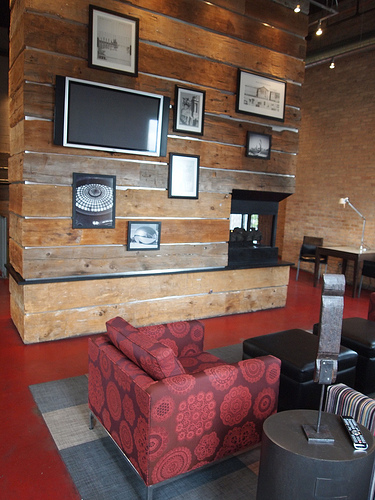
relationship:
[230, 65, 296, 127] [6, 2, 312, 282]
picture hanging from wall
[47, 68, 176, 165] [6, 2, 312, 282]
tv hanging on wall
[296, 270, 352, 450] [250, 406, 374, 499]
lamp on top of table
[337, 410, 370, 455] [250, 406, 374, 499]
remote on top of table